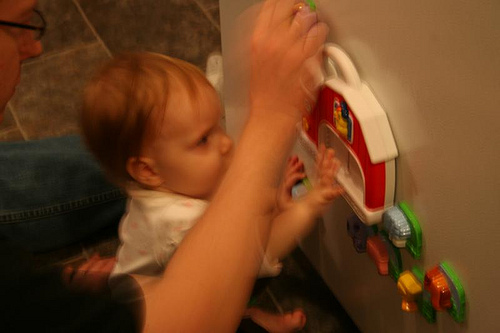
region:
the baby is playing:
[79, 60, 331, 327]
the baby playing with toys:
[81, 40, 359, 331]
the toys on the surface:
[345, 208, 490, 318]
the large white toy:
[295, 32, 412, 232]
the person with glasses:
[1, 1, 330, 328]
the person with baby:
[13, 5, 345, 288]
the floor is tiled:
[51, 8, 197, 46]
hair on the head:
[66, 46, 188, 224]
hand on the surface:
[243, 5, 350, 121]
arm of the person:
[6, 103, 295, 330]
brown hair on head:
[94, 110, 113, 131]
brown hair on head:
[126, 100, 142, 120]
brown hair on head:
[144, 75, 164, 93]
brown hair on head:
[144, 88, 164, 111]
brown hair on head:
[156, 67, 173, 99]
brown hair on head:
[174, 64, 198, 86]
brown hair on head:
[149, 60, 166, 82]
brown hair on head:
[116, 61, 137, 76]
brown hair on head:
[91, 88, 116, 115]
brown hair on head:
[87, 111, 100, 129]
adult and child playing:
[0, 2, 341, 327]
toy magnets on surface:
[285, 40, 465, 322]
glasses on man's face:
[2, 10, 47, 37]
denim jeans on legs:
[1, 136, 116, 251]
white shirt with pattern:
[117, 190, 208, 276]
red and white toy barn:
[302, 78, 396, 224]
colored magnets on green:
[357, 205, 469, 324]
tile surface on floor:
[5, 2, 217, 139]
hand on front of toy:
[306, 145, 341, 209]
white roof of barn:
[332, 77, 399, 162]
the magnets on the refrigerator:
[259, 8, 470, 318]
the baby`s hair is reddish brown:
[50, 28, 222, 183]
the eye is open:
[161, 107, 229, 159]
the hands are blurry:
[185, 0, 368, 265]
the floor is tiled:
[18, 0, 222, 137]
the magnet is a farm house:
[271, 37, 398, 234]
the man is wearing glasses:
[2, 6, 66, 115]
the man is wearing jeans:
[0, 117, 120, 253]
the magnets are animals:
[343, 195, 470, 324]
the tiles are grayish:
[32, 4, 183, 131]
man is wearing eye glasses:
[1, 2, 336, 328]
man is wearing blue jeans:
[0, 129, 164, 236]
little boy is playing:
[61, 39, 479, 322]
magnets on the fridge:
[336, 200, 473, 328]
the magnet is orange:
[422, 267, 456, 311]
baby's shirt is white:
[98, 184, 209, 276]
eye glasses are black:
[1, 8, 51, 43]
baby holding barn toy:
[58, 24, 404, 330]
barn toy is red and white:
[301, 34, 412, 229]